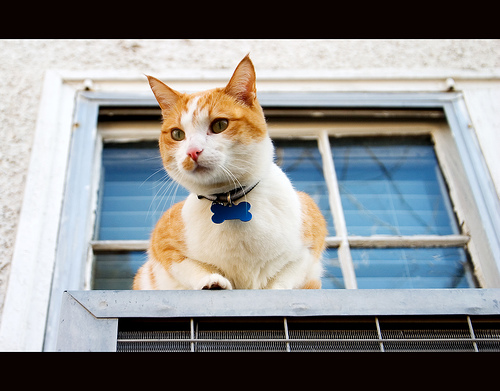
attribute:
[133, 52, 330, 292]
cat — brown, white, orange, furry, tan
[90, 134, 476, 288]
window — clear, shiny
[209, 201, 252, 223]
tag — blue, bone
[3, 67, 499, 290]
frame — white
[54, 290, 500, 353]
air conditioner — silver, metal, gray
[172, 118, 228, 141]
eyes — green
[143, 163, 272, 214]
whisker — white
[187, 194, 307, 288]
chest — white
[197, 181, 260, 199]
collar — black